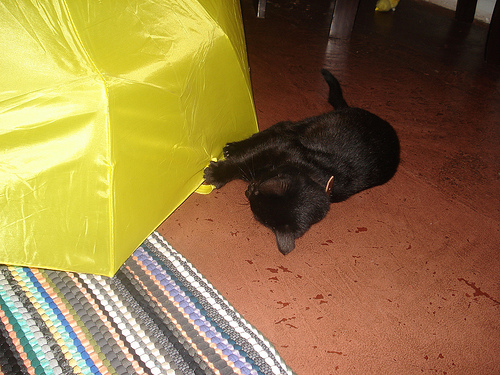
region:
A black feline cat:
[205, 67, 403, 259]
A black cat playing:
[208, 71, 408, 258]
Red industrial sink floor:
[329, 220, 476, 340]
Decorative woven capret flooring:
[1, 228, 292, 373]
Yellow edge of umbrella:
[0, 1, 267, 270]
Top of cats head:
[240, 165, 329, 254]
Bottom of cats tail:
[313, 62, 351, 107]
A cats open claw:
[202, 152, 226, 187]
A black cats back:
[316, 112, 418, 194]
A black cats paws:
[207, 108, 290, 177]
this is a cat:
[205, 52, 428, 253]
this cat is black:
[212, 69, 443, 254]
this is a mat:
[4, 220, 301, 374]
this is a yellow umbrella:
[12, 9, 264, 293]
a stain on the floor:
[447, 266, 498, 327]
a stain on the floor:
[316, 339, 376, 374]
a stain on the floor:
[259, 258, 292, 291]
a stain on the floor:
[218, 220, 250, 250]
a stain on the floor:
[350, 211, 368, 245]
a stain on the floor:
[402, 232, 412, 271]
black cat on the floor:
[200, 60, 406, 257]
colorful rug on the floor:
[117, 290, 214, 350]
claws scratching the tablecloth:
[202, 150, 222, 191]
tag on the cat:
[320, 172, 336, 199]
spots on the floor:
[282, 283, 327, 335]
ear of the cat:
[270, 227, 296, 254]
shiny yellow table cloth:
[43, 63, 125, 166]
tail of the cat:
[311, 59, 343, 108]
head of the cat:
[241, 168, 337, 260]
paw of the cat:
[223, 137, 236, 157]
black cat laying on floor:
[183, 0, 444, 255]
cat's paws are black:
[188, 108, 285, 220]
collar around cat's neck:
[307, 166, 357, 213]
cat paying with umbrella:
[191, 120, 267, 202]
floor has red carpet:
[270, 238, 482, 339]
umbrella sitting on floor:
[98, 85, 197, 213]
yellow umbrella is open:
[4, 6, 285, 283]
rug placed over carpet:
[67, 281, 267, 367]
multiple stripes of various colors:
[82, 297, 250, 362]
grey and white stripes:
[176, 268, 201, 284]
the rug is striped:
[27, 321, 218, 371]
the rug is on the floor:
[147, 248, 272, 368]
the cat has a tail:
[308, 57, 360, 105]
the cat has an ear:
[270, 225, 299, 257]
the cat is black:
[199, 51, 411, 257]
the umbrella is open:
[4, 5, 161, 270]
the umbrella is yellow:
[7, 4, 225, 282]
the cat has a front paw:
[200, 155, 233, 200]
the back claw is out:
[216, 135, 232, 156]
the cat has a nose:
[235, 178, 260, 208]